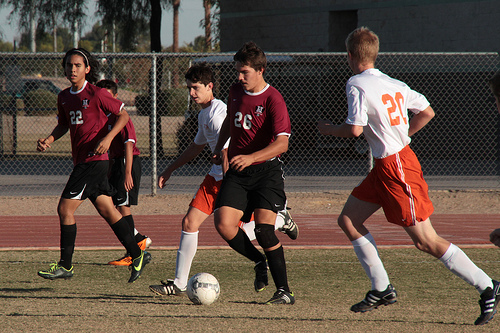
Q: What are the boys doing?
A: Playing soccer.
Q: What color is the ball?
A: White.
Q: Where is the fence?
A: Behind the boys.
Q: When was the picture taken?
A: Daytime.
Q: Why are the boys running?
A: Playing soccer.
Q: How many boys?
A: 5.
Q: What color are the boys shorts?
A: Orange.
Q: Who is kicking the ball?
A: The boy.